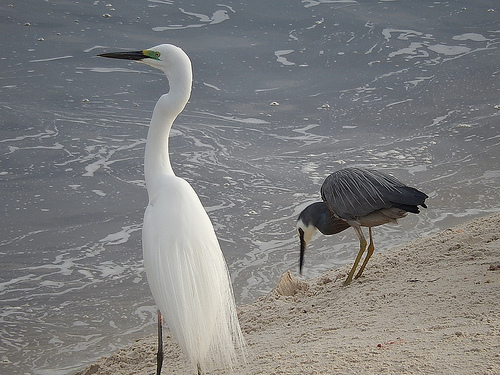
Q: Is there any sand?
A: Yes, there is sand.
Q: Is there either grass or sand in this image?
A: Yes, there is sand.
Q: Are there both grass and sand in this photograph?
A: No, there is sand but no grass.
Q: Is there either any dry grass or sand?
A: Yes, there is dry sand.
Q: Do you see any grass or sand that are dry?
A: Yes, the sand is dry.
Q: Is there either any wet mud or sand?
A: Yes, there is wet sand.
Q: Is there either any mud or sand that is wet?
A: Yes, the sand is wet.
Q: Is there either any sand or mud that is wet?
A: Yes, the sand is wet.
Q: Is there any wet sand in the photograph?
A: Yes, there is wet sand.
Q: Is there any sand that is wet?
A: Yes, there is sand that is wet.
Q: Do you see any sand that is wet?
A: Yes, there is sand that is wet.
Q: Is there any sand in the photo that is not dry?
A: Yes, there is wet sand.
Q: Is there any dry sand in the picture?
A: Yes, there is dry sand.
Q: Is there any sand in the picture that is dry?
A: Yes, there is sand that is dry.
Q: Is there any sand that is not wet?
A: Yes, there is dry sand.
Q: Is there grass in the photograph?
A: No, there is no grass.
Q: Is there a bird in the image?
A: Yes, there is a bird.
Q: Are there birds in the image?
A: Yes, there is a bird.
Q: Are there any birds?
A: Yes, there is a bird.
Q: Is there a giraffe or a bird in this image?
A: Yes, there is a bird.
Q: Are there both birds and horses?
A: No, there is a bird but no horses.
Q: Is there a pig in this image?
A: No, there are no pigs.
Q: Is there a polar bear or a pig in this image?
A: No, there are no pigs or polar bears.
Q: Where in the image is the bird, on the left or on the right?
A: The bird is on the right of the image.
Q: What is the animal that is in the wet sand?
A: The animal is a bird.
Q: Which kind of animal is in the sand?
A: The animal is a bird.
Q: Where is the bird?
A: The bird is in the sand.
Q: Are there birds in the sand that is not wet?
A: Yes, there is a bird in the sand.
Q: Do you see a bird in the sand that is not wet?
A: Yes, there is a bird in the sand.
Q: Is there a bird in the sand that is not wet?
A: Yes, there is a bird in the sand.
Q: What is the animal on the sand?
A: The animal is a bird.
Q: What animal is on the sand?
A: The animal is a bird.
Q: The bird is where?
A: The bird is on the sand.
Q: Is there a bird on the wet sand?
A: Yes, there is a bird on the sand.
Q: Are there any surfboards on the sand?
A: No, there is a bird on the sand.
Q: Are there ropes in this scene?
A: No, there are no ropes.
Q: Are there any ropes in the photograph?
A: No, there are no ropes.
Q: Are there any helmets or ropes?
A: No, there are no ropes or helmets.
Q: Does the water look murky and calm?
A: Yes, the water is murky and calm.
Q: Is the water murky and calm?
A: Yes, the water is murky and calm.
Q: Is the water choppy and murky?
A: No, the water is murky but calm.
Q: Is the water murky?
A: Yes, the water is murky.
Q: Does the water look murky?
A: Yes, the water is murky.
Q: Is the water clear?
A: No, the water is murky.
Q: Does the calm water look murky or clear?
A: The water is murky.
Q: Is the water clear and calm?
A: No, the water is calm but murky.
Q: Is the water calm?
A: Yes, the water is calm.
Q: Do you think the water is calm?
A: Yes, the water is calm.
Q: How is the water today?
A: The water is calm.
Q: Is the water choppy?
A: No, the water is calm.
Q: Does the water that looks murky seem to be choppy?
A: No, the water is calm.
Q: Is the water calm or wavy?
A: The water is calm.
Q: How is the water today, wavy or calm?
A: The water is calm.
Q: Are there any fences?
A: No, there are no fences.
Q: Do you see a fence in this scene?
A: No, there are no fences.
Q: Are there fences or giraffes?
A: No, there are no fences or giraffes.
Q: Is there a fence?
A: No, there are no fences.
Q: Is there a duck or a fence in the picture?
A: No, there are no fences or ducks.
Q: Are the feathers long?
A: Yes, the feathers are long.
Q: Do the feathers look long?
A: Yes, the feathers are long.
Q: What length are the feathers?
A: The feathers are long.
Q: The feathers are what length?
A: The feathers are long.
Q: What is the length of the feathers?
A: The feathers are long.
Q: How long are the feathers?
A: The feathers are long.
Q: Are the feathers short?
A: No, the feathers are long.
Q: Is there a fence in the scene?
A: No, there are no fences.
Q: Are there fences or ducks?
A: No, there are no fences or ducks.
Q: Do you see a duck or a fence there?
A: No, there are no fences or ducks.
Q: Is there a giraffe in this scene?
A: No, there are no giraffes.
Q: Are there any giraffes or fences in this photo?
A: No, there are no giraffes or fences.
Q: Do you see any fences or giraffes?
A: No, there are no giraffes or fences.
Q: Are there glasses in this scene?
A: No, there are no glasses.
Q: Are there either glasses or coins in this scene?
A: No, there are no glasses or coins.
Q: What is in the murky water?
A: The bubbles are in the water.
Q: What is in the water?
A: The bubbles are in the water.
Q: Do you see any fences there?
A: No, there are no fences.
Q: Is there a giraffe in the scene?
A: No, there are no giraffes.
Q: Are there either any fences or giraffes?
A: No, there are no giraffes or fences.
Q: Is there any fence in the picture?
A: No, there are no fences.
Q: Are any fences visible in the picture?
A: No, there are no fences.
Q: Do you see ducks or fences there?
A: No, there are no fences or ducks.